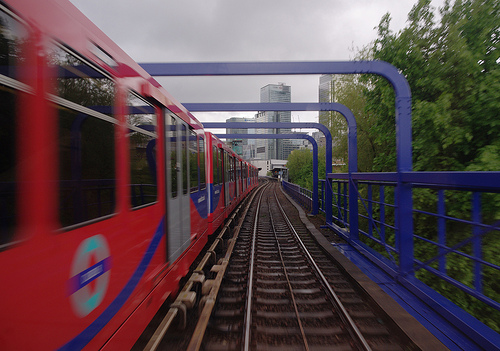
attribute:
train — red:
[1, 2, 261, 348]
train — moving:
[20, 89, 308, 326]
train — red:
[1, 0, 290, 350]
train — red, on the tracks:
[31, 18, 345, 318]